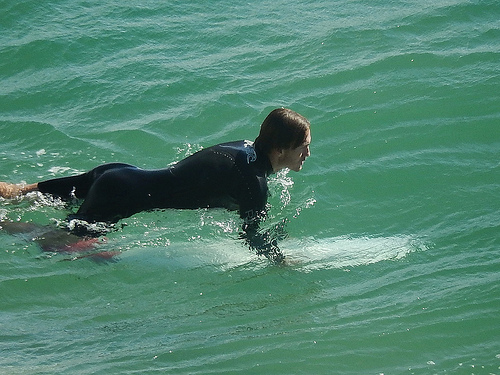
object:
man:
[0, 107, 311, 268]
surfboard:
[117, 234, 430, 273]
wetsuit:
[38, 137, 286, 265]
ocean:
[0, 0, 500, 375]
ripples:
[1, 0, 499, 374]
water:
[0, 0, 500, 375]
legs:
[0, 196, 118, 252]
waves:
[1, 142, 318, 259]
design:
[220, 139, 257, 164]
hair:
[253, 108, 311, 159]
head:
[255, 108, 312, 172]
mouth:
[298, 158, 305, 165]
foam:
[0, 145, 116, 234]